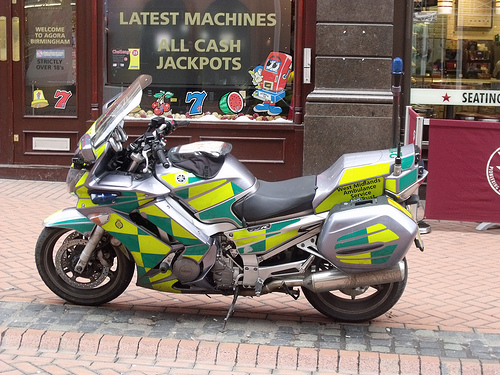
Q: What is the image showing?
A: It is showing a road.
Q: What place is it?
A: It is a road.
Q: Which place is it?
A: It is a road.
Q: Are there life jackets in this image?
A: No, there are no life jackets.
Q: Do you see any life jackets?
A: No, there are no life jackets.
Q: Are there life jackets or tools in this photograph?
A: No, there are no life jackets or tools.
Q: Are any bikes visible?
A: Yes, there is a bike.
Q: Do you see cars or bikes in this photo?
A: Yes, there is a bike.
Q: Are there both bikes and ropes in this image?
A: No, there is a bike but no ropes.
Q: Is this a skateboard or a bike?
A: This is a bike.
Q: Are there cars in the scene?
A: No, there are no cars.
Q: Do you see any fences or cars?
A: No, there are no cars or fences.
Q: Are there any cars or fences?
A: No, there are no cars or fences.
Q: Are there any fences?
A: No, there are no fences.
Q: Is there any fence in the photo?
A: No, there are no fences.